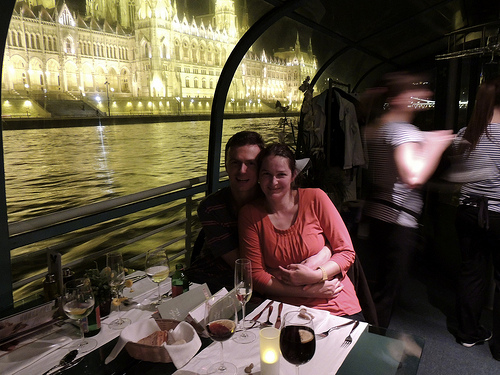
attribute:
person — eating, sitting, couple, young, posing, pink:
[238, 138, 369, 324]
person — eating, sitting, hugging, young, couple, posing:
[187, 127, 268, 293]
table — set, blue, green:
[3, 255, 428, 372]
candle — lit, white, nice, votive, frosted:
[254, 323, 287, 374]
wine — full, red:
[280, 306, 319, 374]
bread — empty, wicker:
[119, 313, 203, 367]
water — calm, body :
[1, 108, 298, 320]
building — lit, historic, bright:
[2, 1, 324, 122]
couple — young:
[188, 130, 365, 323]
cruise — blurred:
[3, 3, 500, 374]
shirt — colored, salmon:
[239, 183, 367, 317]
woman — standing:
[447, 76, 498, 348]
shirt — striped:
[448, 119, 499, 225]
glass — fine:
[229, 255, 256, 344]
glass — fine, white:
[142, 249, 176, 312]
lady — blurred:
[349, 69, 465, 338]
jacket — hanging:
[306, 74, 366, 210]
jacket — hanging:
[337, 86, 366, 132]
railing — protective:
[1, 168, 229, 331]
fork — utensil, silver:
[340, 321, 365, 348]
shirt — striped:
[193, 181, 265, 281]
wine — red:
[201, 294, 247, 372]